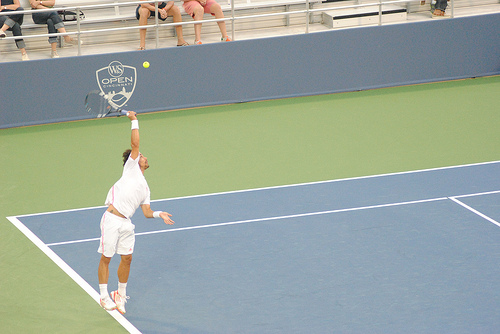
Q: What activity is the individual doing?
A: Playing tennis.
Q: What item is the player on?
A: Tennis court.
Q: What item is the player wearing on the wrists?
A: Wrist bands.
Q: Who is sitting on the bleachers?
A: Spectators.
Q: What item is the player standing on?
A: The court.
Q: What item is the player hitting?
A: A tennis ball.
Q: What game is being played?
A: Tennis.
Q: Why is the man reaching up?
A: To hit.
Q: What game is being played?
A: Tennis.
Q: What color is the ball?
A: Yellow.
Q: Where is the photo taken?
A: Court.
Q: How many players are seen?
A: One.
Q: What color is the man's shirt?
A: White.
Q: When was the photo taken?
A: During match.